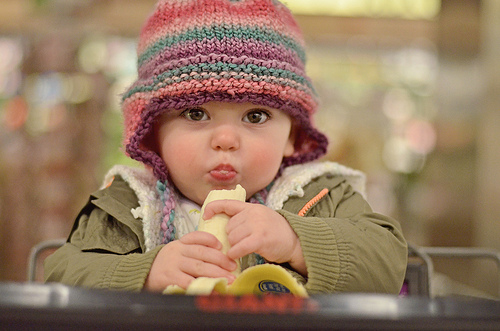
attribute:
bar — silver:
[0, 276, 498, 328]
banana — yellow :
[192, 185, 279, 301]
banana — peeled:
[160, 186, 316, 295]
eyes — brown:
[175, 102, 271, 129]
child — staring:
[43, 0, 408, 295]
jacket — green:
[44, 169, 409, 294]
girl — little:
[44, 0, 417, 316]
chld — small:
[30, 15, 410, 329]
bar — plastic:
[414, 229, 472, 261]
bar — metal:
[420, 239, 499, 286]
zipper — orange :
[290, 185, 337, 218]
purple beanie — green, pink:
[98, 80, 398, 212]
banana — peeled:
[156, 177, 306, 293]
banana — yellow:
[200, 187, 254, 287]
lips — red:
[209, 160, 236, 179]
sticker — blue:
[256, 278, 297, 299]